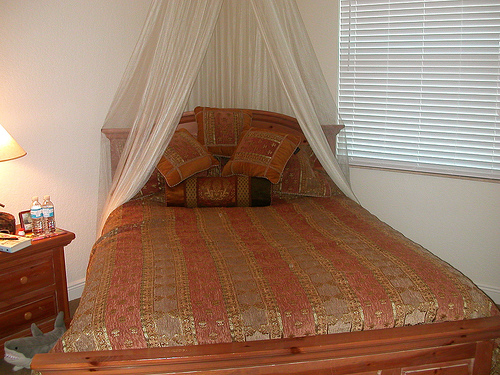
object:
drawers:
[0, 247, 58, 308]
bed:
[31, 106, 499, 373]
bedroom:
[1, 0, 498, 374]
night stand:
[0, 223, 78, 355]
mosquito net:
[95, 0, 361, 240]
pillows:
[136, 126, 220, 189]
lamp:
[0, 126, 28, 233]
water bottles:
[40, 194, 57, 234]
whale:
[0, 310, 67, 374]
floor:
[0, 296, 82, 372]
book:
[0, 232, 33, 254]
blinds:
[336, 0, 499, 184]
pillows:
[220, 113, 304, 185]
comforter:
[48, 192, 500, 354]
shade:
[0, 127, 26, 163]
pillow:
[163, 172, 273, 208]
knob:
[18, 274, 28, 286]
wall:
[0, 0, 155, 301]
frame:
[98, 108, 345, 194]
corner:
[103, 1, 357, 210]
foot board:
[31, 316, 499, 375]